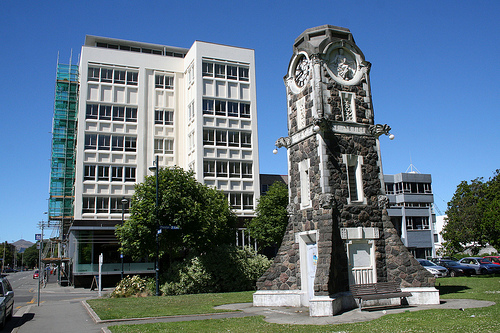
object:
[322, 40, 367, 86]
clock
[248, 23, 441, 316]
tower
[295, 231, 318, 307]
door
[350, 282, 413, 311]
bench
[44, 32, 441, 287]
building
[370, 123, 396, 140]
statue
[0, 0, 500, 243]
sky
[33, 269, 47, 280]
car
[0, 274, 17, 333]
car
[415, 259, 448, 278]
cars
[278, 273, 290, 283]
stone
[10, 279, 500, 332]
sidewalk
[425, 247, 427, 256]
line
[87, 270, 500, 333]
grass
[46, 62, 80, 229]
fire escape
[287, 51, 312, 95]
face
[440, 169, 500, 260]
trees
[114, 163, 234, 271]
trees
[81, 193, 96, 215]
windows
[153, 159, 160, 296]
pole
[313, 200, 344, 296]
pillar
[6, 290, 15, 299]
mirror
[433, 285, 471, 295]
shadow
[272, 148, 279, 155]
light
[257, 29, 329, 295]
side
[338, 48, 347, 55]
figure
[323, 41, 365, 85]
face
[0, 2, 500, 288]
background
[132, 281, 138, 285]
flowers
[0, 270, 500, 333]
ground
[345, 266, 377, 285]
rail